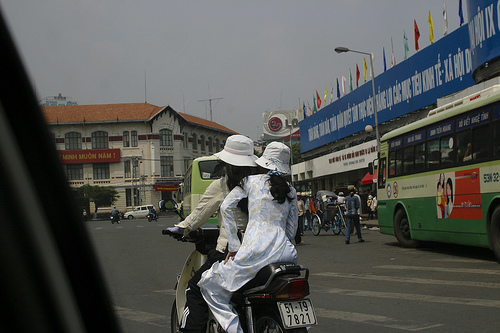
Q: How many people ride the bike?
A: Two.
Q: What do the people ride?
A: A bike.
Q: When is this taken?
A: During the day.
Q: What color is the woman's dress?
A: White.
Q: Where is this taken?
A: On a street.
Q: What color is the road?
A: Black.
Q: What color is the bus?
A: Green.